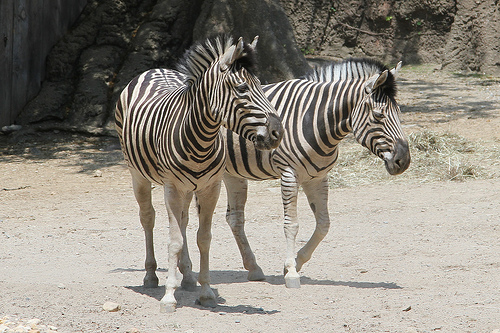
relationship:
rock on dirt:
[97, 294, 123, 317] [8, 153, 499, 330]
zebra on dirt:
[113, 35, 284, 313] [78, 211, 460, 325]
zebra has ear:
[113, 35, 284, 313] [222, 28, 262, 65]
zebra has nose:
[113, 35, 284, 313] [252, 114, 309, 164]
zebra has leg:
[113, 35, 284, 313] [195, 174, 231, 308]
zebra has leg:
[113, 35, 284, 313] [156, 181, 193, 314]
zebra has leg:
[113, 35, 284, 313] [129, 163, 161, 293]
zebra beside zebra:
[81, 52, 243, 203] [288, 50, 414, 223]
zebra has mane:
[113, 35, 284, 313] [168, 26, 261, 93]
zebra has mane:
[210, 50, 417, 290] [297, 52, 402, 104]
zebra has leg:
[113, 35, 284, 313] [195, 173, 222, 309]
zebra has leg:
[113, 35, 284, 313] [158, 181, 183, 314]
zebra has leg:
[113, 35, 284, 313] [176, 185, 199, 292]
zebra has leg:
[113, 35, 284, 313] [125, 164, 161, 289]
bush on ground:
[345, 127, 485, 182] [0, 60, 497, 331]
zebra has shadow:
[113, 35, 284, 313] [126, 279, 276, 314]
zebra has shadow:
[178, 50, 418, 291] [118, 264, 403, 291]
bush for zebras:
[345, 127, 485, 182] [115, 32, 424, 304]